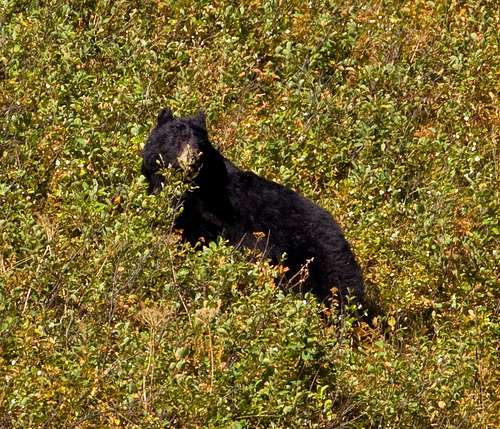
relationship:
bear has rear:
[141, 106, 364, 315] [323, 212, 367, 310]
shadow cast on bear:
[175, 151, 234, 242] [141, 106, 364, 315]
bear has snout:
[141, 106, 364, 315] [179, 145, 203, 172]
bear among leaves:
[141, 106, 364, 315] [1, 1, 499, 429]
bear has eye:
[141, 106, 364, 315] [179, 135, 188, 146]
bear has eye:
[141, 106, 364, 315] [200, 141, 206, 152]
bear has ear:
[141, 106, 364, 315] [157, 106, 174, 127]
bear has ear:
[141, 106, 364, 315] [192, 110, 205, 128]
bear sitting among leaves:
[141, 106, 364, 315] [1, 1, 499, 429]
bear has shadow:
[141, 106, 364, 315] [362, 288, 422, 359]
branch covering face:
[152, 146, 201, 213] [170, 128, 206, 178]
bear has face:
[141, 106, 364, 315] [170, 128, 206, 178]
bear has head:
[141, 106, 364, 315] [143, 107, 208, 192]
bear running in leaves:
[141, 106, 364, 315] [1, 1, 499, 429]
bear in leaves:
[141, 106, 364, 315] [1, 1, 499, 429]